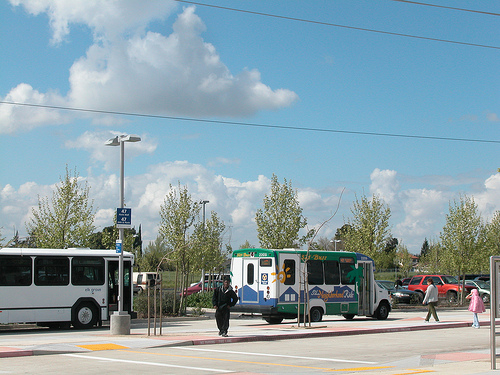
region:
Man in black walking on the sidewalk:
[208, 271, 242, 338]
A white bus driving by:
[3, 248, 138, 331]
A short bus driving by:
[230, 246, 397, 323]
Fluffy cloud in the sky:
[8, 2, 301, 129]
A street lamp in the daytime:
[103, 131, 141, 334]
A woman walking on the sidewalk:
[417, 275, 444, 325]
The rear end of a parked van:
[133, 268, 163, 295]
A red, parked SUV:
[407, 270, 478, 304]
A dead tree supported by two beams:
[146, 238, 187, 338]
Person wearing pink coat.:
[470, 292, 487, 310]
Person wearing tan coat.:
[422, 286, 439, 298]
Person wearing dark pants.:
[419, 303, 441, 320]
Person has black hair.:
[217, 276, 245, 288]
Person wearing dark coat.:
[203, 286, 248, 315]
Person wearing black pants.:
[211, 311, 235, 326]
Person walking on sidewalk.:
[207, 321, 237, 340]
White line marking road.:
[256, 334, 301, 360]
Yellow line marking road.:
[213, 353, 269, 373]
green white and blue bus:
[233, 229, 402, 334]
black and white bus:
[9, 245, 131, 322]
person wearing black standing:
[200, 283, 245, 350]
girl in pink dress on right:
[462, 278, 486, 339]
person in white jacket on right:
[417, 275, 455, 333]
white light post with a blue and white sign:
[81, 110, 163, 228]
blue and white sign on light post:
[112, 201, 152, 228]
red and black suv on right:
[408, 266, 470, 302]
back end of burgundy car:
[182, 275, 232, 304]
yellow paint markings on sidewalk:
[79, 341, 126, 354]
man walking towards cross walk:
[208, 273, 240, 341]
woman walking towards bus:
[417, 275, 441, 325]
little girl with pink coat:
[463, 285, 489, 330]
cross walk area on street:
[69, 333, 409, 373]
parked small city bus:
[226, 241, 393, 323]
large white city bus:
[0, 242, 140, 331]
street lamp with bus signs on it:
[100, 129, 142, 332]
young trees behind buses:
[21, 158, 491, 301]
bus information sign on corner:
[481, 248, 498, 374]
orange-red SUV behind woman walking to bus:
[407, 270, 474, 304]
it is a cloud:
[52, 4, 372, 109]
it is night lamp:
[94, 128, 143, 146]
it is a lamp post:
[99, 124, 146, 331]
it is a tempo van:
[233, 243, 395, 315]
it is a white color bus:
[4, 247, 142, 332]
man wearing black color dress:
[212, 274, 247, 344]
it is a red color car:
[404, 274, 476, 302]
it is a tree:
[166, 193, 198, 314]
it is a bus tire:
[68, 298, 102, 329]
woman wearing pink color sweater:
[467, 289, 487, 315]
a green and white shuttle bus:
[226, 247, 391, 323]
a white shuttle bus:
[1, 249, 138, 331]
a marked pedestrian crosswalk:
[66, 344, 376, 371]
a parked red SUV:
[408, 273, 476, 299]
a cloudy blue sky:
[2, 1, 499, 256]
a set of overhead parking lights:
[103, 134, 141, 146]